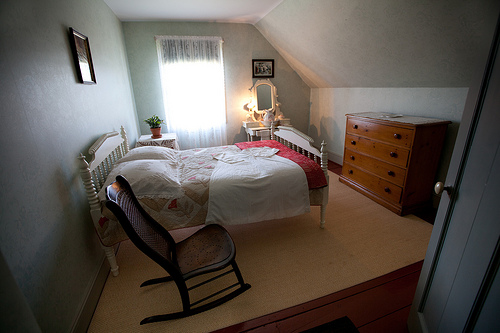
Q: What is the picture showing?
A: It is showing a bedroom.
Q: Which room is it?
A: It is a bedroom.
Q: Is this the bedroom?
A: Yes, it is the bedroom.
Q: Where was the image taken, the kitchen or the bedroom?
A: It was taken at the bedroom.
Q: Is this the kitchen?
A: No, it is the bedroom.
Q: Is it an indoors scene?
A: Yes, it is indoors.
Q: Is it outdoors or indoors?
A: It is indoors.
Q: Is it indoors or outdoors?
A: It is indoors.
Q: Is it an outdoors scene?
A: No, it is indoors.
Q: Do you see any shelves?
A: No, there are no shelves.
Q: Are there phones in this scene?
A: No, there are no phones.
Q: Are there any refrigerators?
A: No, there are no refrigerators.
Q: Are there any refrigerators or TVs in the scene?
A: No, there are no refrigerators or tvs.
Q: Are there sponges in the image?
A: No, there are no sponges.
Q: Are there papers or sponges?
A: No, there are no sponges or papers.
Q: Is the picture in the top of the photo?
A: Yes, the picture is in the top of the image.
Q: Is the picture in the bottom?
A: No, the picture is in the top of the image.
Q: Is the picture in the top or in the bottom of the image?
A: The picture is in the top of the image.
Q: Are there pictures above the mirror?
A: Yes, there is a picture above the mirror.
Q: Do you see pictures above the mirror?
A: Yes, there is a picture above the mirror.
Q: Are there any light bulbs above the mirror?
A: No, there is a picture above the mirror.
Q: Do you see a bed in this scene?
A: Yes, there is a bed.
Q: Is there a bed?
A: Yes, there is a bed.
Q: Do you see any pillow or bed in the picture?
A: Yes, there is a bed.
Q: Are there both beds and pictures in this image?
A: Yes, there are both a bed and a picture.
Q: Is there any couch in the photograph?
A: No, there are no couches.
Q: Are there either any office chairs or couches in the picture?
A: No, there are no couches or office chairs.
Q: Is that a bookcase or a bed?
A: That is a bed.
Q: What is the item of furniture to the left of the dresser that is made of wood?
A: The piece of furniture is a bed.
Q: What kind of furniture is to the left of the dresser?
A: The piece of furniture is a bed.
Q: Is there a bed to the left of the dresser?
A: Yes, there is a bed to the left of the dresser.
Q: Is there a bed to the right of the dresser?
A: No, the bed is to the left of the dresser.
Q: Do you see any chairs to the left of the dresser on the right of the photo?
A: No, there is a bed to the left of the dresser.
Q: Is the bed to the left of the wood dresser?
A: Yes, the bed is to the left of the dresser.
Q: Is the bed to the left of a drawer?
A: No, the bed is to the left of the dresser.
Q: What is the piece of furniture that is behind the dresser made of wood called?
A: The piece of furniture is a bed.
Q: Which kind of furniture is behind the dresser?
A: The piece of furniture is a bed.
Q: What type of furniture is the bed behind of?
A: The bed is behind the dresser.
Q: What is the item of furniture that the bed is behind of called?
A: The piece of furniture is a dresser.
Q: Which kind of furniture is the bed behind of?
A: The bed is behind the dresser.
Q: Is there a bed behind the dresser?
A: Yes, there is a bed behind the dresser.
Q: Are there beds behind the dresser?
A: Yes, there is a bed behind the dresser.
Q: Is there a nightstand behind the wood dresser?
A: No, there is a bed behind the dresser.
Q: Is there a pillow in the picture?
A: Yes, there is a pillow.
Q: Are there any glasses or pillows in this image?
A: Yes, there is a pillow.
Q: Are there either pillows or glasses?
A: Yes, there is a pillow.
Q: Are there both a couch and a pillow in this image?
A: No, there is a pillow but no couches.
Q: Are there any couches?
A: No, there are no couches.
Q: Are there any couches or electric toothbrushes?
A: No, there are no couches or electric toothbrushes.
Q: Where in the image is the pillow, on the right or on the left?
A: The pillow is on the left of the image.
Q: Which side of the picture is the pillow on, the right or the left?
A: The pillow is on the left of the image.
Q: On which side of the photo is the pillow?
A: The pillow is on the left of the image.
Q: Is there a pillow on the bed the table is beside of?
A: Yes, there is a pillow on the bed.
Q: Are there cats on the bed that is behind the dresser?
A: No, there is a pillow on the bed.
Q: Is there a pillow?
A: Yes, there is a pillow.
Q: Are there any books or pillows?
A: Yes, there is a pillow.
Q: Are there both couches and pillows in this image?
A: No, there is a pillow but no couches.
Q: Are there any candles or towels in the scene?
A: No, there are no candles or towels.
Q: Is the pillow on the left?
A: Yes, the pillow is on the left of the image.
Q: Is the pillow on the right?
A: No, the pillow is on the left of the image.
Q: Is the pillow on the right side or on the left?
A: The pillow is on the left of the image.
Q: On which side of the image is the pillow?
A: The pillow is on the left of the image.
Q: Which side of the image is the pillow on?
A: The pillow is on the left of the image.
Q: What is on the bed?
A: The pillow is on the bed.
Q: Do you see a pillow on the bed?
A: Yes, there is a pillow on the bed.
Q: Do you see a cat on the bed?
A: No, there is a pillow on the bed.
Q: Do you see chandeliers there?
A: No, there are no chandeliers.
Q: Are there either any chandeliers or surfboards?
A: No, there are no chandeliers or surfboards.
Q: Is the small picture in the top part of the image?
A: Yes, the picture is in the top of the image.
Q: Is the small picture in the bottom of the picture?
A: No, the picture is in the top of the image.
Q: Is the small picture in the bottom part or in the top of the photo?
A: The picture is in the top of the image.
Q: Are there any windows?
A: Yes, there is a window.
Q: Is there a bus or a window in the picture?
A: Yes, there is a window.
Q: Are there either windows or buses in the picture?
A: Yes, there is a window.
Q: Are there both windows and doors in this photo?
A: Yes, there are both a window and a door.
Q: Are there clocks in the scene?
A: No, there are no clocks.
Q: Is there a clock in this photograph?
A: No, there are no clocks.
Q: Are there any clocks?
A: No, there are no clocks.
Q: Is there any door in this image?
A: Yes, there is a door.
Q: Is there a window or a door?
A: Yes, there is a door.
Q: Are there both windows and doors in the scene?
A: Yes, there are both a door and a window.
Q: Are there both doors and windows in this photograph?
A: Yes, there are both a door and a window.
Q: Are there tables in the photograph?
A: Yes, there is a table.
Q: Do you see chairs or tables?
A: Yes, there is a table.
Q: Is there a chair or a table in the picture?
A: Yes, there is a table.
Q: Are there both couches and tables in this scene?
A: No, there is a table but no couches.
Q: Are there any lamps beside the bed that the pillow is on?
A: No, there is a table beside the bed.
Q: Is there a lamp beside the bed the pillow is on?
A: No, there is a table beside the bed.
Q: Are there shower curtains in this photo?
A: No, there are no shower curtains.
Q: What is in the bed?
A: The quilt is in the bed.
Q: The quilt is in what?
A: The quilt is in the bed.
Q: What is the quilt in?
A: The quilt is in the bed.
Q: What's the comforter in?
A: The quilt is in the bed.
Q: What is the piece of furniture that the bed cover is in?
A: The piece of furniture is a bed.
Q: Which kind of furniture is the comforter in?
A: The bed cover is in the bed.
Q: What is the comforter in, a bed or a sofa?
A: The comforter is in a bed.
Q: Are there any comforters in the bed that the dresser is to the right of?
A: Yes, there is a comforter in the bed.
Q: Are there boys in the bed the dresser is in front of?
A: No, there is a comforter in the bed.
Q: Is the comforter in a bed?
A: Yes, the comforter is in a bed.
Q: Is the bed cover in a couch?
A: No, the bed cover is in a bed.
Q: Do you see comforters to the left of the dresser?
A: Yes, there is a comforter to the left of the dresser.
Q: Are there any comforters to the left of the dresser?
A: Yes, there is a comforter to the left of the dresser.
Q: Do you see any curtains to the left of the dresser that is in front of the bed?
A: No, there is a comforter to the left of the dresser.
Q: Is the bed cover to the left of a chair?
A: No, the bed cover is to the left of the dresser.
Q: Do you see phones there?
A: No, there are no phones.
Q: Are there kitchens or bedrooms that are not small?
A: No, there is a bedroom but it is small.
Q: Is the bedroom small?
A: Yes, the bedroom is small.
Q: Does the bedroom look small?
A: Yes, the bedroom is small.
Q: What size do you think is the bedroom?
A: The bedroom is small.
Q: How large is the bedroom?
A: The bedroom is small.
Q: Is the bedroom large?
A: No, the bedroom is small.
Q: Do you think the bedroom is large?
A: No, the bedroom is small.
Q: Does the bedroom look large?
A: No, the bedroom is small.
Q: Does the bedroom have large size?
A: No, the bedroom is small.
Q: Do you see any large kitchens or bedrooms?
A: No, there is a bedroom but it is small.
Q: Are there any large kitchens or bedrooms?
A: No, there is a bedroom but it is small.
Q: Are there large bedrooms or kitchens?
A: No, there is a bedroom but it is small.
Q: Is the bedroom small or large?
A: The bedroom is small.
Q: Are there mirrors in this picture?
A: Yes, there is a mirror.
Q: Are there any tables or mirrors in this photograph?
A: Yes, there is a mirror.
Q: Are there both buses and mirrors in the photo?
A: No, there is a mirror but no buses.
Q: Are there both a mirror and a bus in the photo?
A: No, there is a mirror but no buses.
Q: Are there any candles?
A: No, there are no candles.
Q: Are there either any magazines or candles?
A: No, there are no candles or magazines.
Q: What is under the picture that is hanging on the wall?
A: The mirror is under the picture.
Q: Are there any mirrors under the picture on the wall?
A: Yes, there is a mirror under the picture.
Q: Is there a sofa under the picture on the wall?
A: No, there is a mirror under the picture.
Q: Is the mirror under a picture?
A: Yes, the mirror is under a picture.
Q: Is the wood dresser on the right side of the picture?
A: Yes, the dresser is on the right of the image.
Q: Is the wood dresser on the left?
A: No, the dresser is on the right of the image.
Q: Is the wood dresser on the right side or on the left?
A: The dresser is on the right of the image.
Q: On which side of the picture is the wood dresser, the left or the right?
A: The dresser is on the right of the image.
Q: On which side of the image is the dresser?
A: The dresser is on the right of the image.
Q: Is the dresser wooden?
A: Yes, the dresser is wooden.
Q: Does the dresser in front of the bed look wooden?
A: Yes, the dresser is wooden.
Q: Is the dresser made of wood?
A: Yes, the dresser is made of wood.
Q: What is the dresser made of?
A: The dresser is made of wood.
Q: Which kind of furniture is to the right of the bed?
A: The piece of furniture is a dresser.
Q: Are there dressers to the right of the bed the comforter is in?
A: Yes, there is a dresser to the right of the bed.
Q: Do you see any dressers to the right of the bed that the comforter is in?
A: Yes, there is a dresser to the right of the bed.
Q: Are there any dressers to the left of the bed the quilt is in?
A: No, the dresser is to the right of the bed.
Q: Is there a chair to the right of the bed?
A: No, there is a dresser to the right of the bed.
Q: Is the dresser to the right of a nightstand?
A: No, the dresser is to the right of the bed.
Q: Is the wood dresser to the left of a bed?
A: No, the dresser is to the right of a bed.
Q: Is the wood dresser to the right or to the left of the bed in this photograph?
A: The dresser is to the right of the bed.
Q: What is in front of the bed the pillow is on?
A: The dresser is in front of the bed.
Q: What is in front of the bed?
A: The dresser is in front of the bed.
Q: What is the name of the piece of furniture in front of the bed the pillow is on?
A: The piece of furniture is a dresser.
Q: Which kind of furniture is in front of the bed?
A: The piece of furniture is a dresser.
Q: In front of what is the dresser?
A: The dresser is in front of the bed.